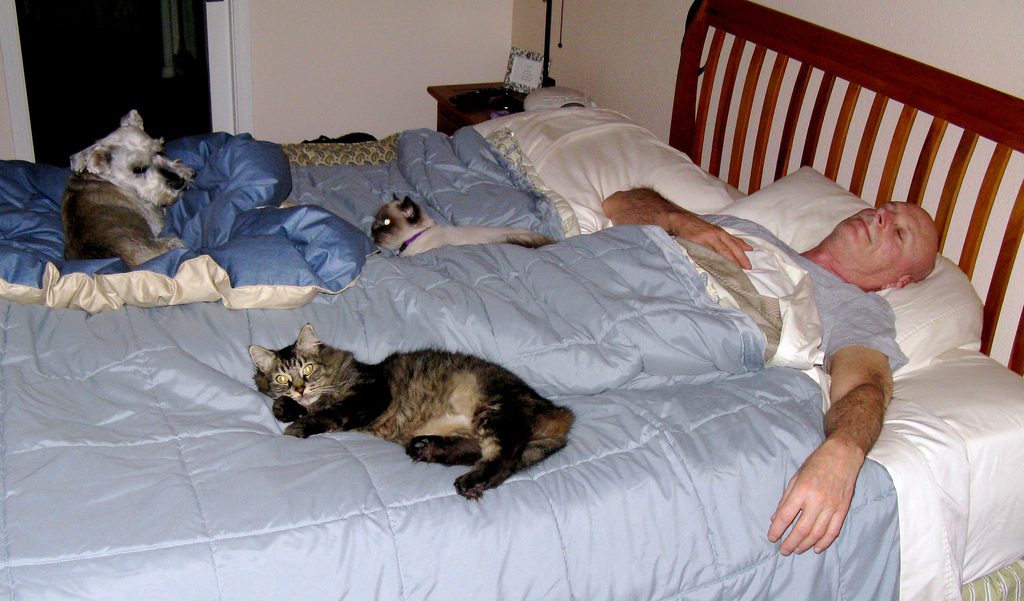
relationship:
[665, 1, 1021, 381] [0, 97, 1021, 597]
headboard on bed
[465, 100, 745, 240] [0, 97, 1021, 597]
pillow on bed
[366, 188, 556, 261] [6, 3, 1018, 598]
animal on bed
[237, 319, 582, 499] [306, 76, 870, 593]
cat on bed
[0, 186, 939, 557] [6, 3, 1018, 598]
person on bed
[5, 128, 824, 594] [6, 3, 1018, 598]
sheets on bed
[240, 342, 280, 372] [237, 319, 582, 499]
ear on cat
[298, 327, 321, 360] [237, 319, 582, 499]
ear on cat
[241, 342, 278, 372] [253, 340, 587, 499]
ear on cat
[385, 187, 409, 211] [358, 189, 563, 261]
ear on cat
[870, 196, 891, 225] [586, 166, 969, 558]
nose on man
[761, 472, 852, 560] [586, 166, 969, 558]
finger on man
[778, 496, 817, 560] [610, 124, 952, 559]
finger on man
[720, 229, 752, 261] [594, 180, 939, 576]
finger on man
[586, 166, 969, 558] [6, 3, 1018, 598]
man on bed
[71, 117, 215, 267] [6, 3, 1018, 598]
dog on bed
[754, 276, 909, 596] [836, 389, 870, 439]
hand has hair